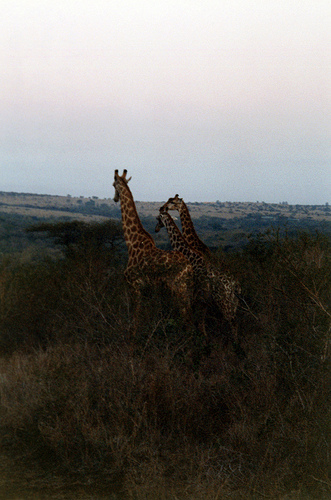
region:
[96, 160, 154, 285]
spotted giraffe in wild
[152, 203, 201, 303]
spotted giraffe in wild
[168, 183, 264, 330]
spotted giraffe in wild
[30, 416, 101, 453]
green and brown grass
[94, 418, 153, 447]
green and brown grass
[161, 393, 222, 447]
green and brown grass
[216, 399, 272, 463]
green and brown grass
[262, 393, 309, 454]
green and brown grass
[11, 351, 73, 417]
green and brown grass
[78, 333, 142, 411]
green and brown grass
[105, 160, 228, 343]
the giraffes are two in number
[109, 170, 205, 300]
the giraffes are standing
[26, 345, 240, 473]
grass are all over the place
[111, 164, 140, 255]
the neck is tall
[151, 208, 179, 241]
the giraffe is short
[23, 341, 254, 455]
the grass are brown in color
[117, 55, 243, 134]
the sky is white in color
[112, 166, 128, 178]
these are the horns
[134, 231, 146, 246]
the giraffe is brown and white incolor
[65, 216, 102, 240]
the tree is green in color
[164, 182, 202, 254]
spotted giraffe in wild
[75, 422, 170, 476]
green and brown grass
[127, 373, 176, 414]
green and brown grass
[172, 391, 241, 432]
green and brown grass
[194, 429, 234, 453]
green and brown grass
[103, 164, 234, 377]
three giraffes are in field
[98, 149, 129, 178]
brown and orange horns on giraffe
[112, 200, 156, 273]
orange and brown spots on giraffe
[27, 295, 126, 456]
grass is brown and wiry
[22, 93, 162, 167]
sky is grey and cloudy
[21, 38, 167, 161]
thick grey clouds are in sky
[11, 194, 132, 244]
large brown field off in distance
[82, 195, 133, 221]
green trees in field off in distance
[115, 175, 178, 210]
giraffes' faces are light colored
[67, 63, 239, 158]
light blue hue to sky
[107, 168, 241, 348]
three giraffes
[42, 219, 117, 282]
a tree in the grass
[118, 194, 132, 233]
the giraffes neck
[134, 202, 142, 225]
hair on the giraffe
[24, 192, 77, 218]
dirt on the hill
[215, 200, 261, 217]
green bushes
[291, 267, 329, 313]
tree branches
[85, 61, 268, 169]
the sky is clear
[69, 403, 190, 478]
the grass is dry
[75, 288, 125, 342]
a tree branch